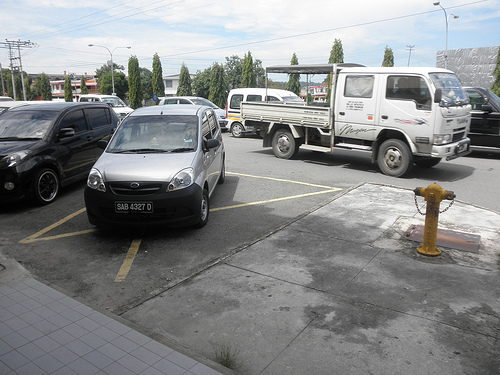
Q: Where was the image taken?
A: It was taken at the pavement.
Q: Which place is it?
A: It is a pavement.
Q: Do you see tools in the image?
A: No, there are no tools.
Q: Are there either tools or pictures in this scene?
A: No, there are no tools or pictures.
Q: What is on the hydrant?
A: The chain is on the hydrant.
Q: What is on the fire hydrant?
A: The chain is on the hydrant.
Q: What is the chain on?
A: The chain is on the hydrant.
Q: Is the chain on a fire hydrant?
A: Yes, the chain is on a fire hydrant.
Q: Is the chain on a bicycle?
A: No, the chain is on a fire hydrant.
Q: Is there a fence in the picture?
A: No, there are no fences.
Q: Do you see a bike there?
A: No, there are no bikes.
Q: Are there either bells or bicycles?
A: No, there are no bicycles or bells.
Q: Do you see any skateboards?
A: No, there are no skateboards.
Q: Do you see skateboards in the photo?
A: No, there are no skateboards.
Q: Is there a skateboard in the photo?
A: No, there are no skateboards.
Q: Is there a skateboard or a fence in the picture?
A: No, there are no skateboards or fences.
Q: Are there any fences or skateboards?
A: No, there are no skateboards or fences.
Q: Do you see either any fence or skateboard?
A: No, there are no skateboards or fences.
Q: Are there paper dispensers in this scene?
A: No, there are no paper dispensers.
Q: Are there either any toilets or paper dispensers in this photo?
A: No, there are no paper dispensers or toilets.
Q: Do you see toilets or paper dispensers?
A: No, there are no paper dispensers or toilets.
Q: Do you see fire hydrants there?
A: Yes, there is a fire hydrant.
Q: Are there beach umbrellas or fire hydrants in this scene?
A: Yes, there is a fire hydrant.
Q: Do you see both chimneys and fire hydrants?
A: No, there is a fire hydrant but no chimneys.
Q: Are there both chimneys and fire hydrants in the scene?
A: No, there is a fire hydrant but no chimneys.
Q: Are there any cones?
A: No, there are no cones.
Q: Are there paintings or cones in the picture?
A: No, there are no cones or paintings.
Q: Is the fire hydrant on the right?
A: Yes, the fire hydrant is on the right of the image.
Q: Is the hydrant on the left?
A: No, the hydrant is on the right of the image.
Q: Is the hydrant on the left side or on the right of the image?
A: The hydrant is on the right of the image.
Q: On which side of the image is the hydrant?
A: The hydrant is on the right of the image.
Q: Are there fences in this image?
A: No, there are no fences.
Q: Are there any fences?
A: No, there are no fences.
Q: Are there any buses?
A: No, there are no buses.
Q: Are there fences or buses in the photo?
A: No, there are no buses or fences.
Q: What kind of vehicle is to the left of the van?
A: The vehicle is a car.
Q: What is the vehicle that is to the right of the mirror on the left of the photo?
A: The vehicle is a car.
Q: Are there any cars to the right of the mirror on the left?
A: Yes, there is a car to the right of the mirror.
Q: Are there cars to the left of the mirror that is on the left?
A: No, the car is to the right of the mirror.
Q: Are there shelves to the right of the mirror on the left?
A: No, there is a car to the right of the mirror.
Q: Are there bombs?
A: No, there are no bombs.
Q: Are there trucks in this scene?
A: Yes, there is a truck.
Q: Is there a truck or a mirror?
A: Yes, there is a truck.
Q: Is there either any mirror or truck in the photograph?
A: Yes, there is a truck.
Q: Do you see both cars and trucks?
A: Yes, there are both a truck and a car.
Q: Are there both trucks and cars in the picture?
A: Yes, there are both a truck and a car.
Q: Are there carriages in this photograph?
A: No, there are no carriages.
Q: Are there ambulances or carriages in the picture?
A: No, there are no carriages or ambulances.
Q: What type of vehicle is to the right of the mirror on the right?
A: The vehicle is a truck.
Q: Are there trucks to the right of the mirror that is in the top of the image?
A: Yes, there is a truck to the right of the mirror.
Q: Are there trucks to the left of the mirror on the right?
A: No, the truck is to the right of the mirror.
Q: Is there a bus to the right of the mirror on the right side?
A: No, there is a truck to the right of the mirror.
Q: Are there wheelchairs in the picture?
A: No, there are no wheelchairs.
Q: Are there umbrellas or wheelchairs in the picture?
A: No, there are no wheelchairs or umbrellas.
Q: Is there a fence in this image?
A: No, there are no fences.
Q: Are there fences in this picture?
A: No, there are no fences.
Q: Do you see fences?
A: No, there are no fences.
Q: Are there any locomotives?
A: No, there are no locomotives.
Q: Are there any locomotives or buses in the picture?
A: No, there are no locomotives or buses.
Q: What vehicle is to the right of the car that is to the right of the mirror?
A: The vehicle is a van.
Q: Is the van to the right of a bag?
A: No, the van is to the right of the car.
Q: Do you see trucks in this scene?
A: Yes, there is a truck.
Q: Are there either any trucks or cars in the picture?
A: Yes, there is a truck.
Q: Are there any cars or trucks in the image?
A: Yes, there is a truck.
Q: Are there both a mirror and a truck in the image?
A: Yes, there are both a truck and a mirror.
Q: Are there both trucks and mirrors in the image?
A: Yes, there are both a truck and a mirror.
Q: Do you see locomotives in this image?
A: No, there are no locomotives.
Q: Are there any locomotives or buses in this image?
A: No, there are no locomotives or buses.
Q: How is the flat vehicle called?
A: The vehicle is a truck.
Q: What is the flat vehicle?
A: The vehicle is a truck.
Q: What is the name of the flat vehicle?
A: The vehicle is a truck.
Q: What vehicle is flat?
A: The vehicle is a truck.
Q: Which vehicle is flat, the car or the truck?
A: The truck is flat.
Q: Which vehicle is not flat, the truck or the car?
A: The car is not flat.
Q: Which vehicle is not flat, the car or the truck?
A: The car is not flat.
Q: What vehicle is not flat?
A: The vehicle is a car.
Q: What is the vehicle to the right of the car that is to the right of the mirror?
A: The vehicle is a truck.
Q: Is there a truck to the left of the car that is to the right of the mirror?
A: No, the truck is to the right of the car.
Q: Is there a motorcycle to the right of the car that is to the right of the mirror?
A: No, there is a truck to the right of the car.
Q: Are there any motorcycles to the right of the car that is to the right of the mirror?
A: No, there is a truck to the right of the car.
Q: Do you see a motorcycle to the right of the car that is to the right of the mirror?
A: No, there is a truck to the right of the car.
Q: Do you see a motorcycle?
A: No, there are no motorcycles.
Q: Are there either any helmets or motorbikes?
A: No, there are no motorbikes or helmets.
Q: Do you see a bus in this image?
A: No, there are no buses.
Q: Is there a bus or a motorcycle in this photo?
A: No, there are no buses or motorcycles.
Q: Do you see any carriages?
A: No, there are no carriages.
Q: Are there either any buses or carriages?
A: No, there are no carriages or buses.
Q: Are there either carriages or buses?
A: No, there are no carriages or buses.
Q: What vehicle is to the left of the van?
A: The vehicle is a car.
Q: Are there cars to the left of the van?
A: Yes, there is a car to the left of the van.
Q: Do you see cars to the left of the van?
A: Yes, there is a car to the left of the van.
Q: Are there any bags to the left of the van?
A: No, there is a car to the left of the van.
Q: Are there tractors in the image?
A: No, there are no tractors.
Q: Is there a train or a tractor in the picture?
A: No, there are no tractors or trains.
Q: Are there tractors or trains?
A: No, there are no tractors or trains.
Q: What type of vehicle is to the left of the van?
A: The vehicle is a car.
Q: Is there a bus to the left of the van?
A: No, there is a car to the left of the van.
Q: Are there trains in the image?
A: No, there are no trains.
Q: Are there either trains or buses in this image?
A: No, there are no trains or buses.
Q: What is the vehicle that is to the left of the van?
A: The vehicle is a car.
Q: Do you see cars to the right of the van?
A: No, the car is to the left of the van.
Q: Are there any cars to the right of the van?
A: No, the car is to the left of the van.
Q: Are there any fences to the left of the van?
A: No, there is a car to the left of the van.